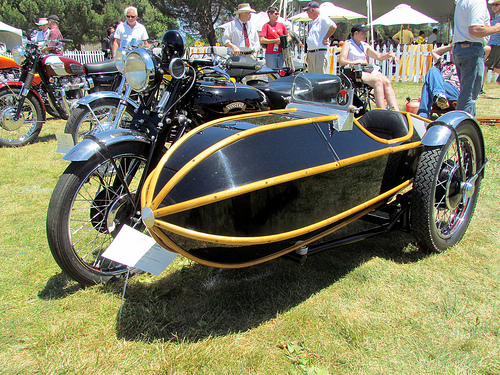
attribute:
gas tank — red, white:
[215, 86, 255, 122]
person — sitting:
[340, 15, 445, 135]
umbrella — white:
[362, 2, 442, 31]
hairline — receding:
[125, 3, 140, 10]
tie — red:
[235, 20, 252, 44]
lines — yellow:
[189, 145, 275, 212]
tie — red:
[209, 14, 288, 68]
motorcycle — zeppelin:
[59, 65, 472, 275]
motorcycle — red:
[21, 58, 113, 120]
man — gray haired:
[106, 0, 180, 74]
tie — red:
[232, 19, 267, 63]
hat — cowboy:
[213, 0, 262, 10]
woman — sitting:
[336, 27, 407, 101]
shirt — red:
[251, 22, 297, 49]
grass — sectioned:
[290, 246, 495, 357]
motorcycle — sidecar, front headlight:
[42, 43, 484, 305]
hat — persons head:
[352, 14, 374, 31]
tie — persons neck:
[242, 22, 251, 55]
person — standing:
[255, 9, 286, 84]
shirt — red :
[258, 20, 288, 50]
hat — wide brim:
[225, 4, 258, 14]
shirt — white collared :
[221, 12, 260, 49]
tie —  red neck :
[241, 26, 254, 52]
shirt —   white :
[336, 35, 385, 70]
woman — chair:
[347, 26, 402, 114]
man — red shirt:
[258, 4, 290, 71]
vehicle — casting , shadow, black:
[35, 53, 484, 295]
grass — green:
[315, 290, 479, 363]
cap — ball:
[296, 3, 322, 13]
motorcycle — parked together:
[4, 40, 159, 156]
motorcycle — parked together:
[71, 54, 346, 157]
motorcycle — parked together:
[42, 86, 484, 288]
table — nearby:
[388, 51, 432, 74]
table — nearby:
[304, 41, 349, 62]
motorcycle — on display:
[52, 69, 484, 286]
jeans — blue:
[451, 46, 484, 109]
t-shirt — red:
[263, 21, 287, 55]